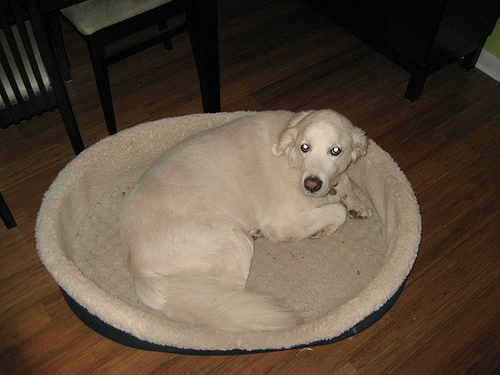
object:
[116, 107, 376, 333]
dog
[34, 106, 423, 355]
bed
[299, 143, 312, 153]
eye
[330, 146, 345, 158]
eye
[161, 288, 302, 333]
tail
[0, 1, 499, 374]
floor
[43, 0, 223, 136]
chair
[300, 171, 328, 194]
snout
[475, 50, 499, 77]
trim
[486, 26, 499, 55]
wall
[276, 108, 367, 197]
head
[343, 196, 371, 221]
paw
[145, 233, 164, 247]
hair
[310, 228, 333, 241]
paw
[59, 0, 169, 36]
cushion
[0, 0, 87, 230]
chair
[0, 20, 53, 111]
cushion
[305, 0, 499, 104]
cabinet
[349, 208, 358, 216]
pad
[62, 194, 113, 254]
inside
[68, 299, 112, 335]
outside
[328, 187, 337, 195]
tag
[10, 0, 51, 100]
spindle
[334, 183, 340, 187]
collar